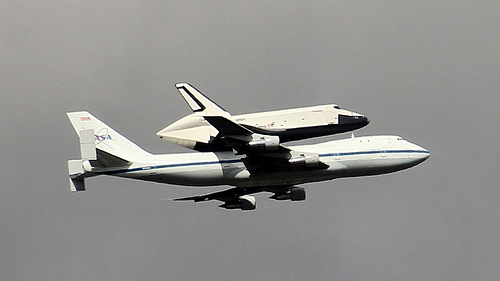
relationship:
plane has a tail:
[66, 110, 431, 209] [66, 110, 153, 164]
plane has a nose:
[66, 110, 431, 209] [404, 141, 431, 170]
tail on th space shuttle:
[174, 81, 232, 118] [156, 81, 369, 151]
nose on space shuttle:
[347, 111, 370, 130] [156, 81, 369, 151]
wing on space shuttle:
[202, 114, 255, 135] [156, 81, 369, 151]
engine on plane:
[284, 151, 320, 169] [66, 110, 431, 209]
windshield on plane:
[395, 137, 405, 141] [66, 110, 431, 209]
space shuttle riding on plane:
[156, 81, 369, 151] [66, 110, 431, 209]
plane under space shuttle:
[66, 110, 431, 209] [156, 81, 369, 151]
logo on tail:
[92, 126, 114, 146] [66, 110, 153, 164]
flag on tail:
[80, 116, 92, 121] [66, 110, 153, 164]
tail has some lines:
[174, 81, 232, 118] [175, 81, 229, 114]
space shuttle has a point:
[156, 81, 369, 151] [155, 123, 178, 143]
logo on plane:
[92, 126, 114, 146] [66, 110, 431, 209]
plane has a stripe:
[66, 110, 431, 209] [94, 149, 430, 176]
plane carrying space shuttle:
[66, 110, 431, 209] [156, 81, 369, 151]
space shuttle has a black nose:
[156, 81, 369, 151] [404, 141, 431, 170]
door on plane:
[380, 144, 389, 156] [66, 110, 431, 209]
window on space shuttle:
[333, 104, 341, 110] [156, 81, 369, 151]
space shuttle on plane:
[156, 81, 369, 151] [66, 110, 431, 209]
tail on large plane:
[66, 110, 153, 164] [66, 110, 431, 209]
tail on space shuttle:
[174, 81, 232, 118] [156, 81, 369, 151]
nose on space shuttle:
[404, 141, 431, 170] [156, 81, 369, 151]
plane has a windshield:
[66, 110, 431, 209] [395, 137, 405, 141]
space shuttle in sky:
[156, 81, 369, 151] [0, 0, 499, 280]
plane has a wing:
[66, 110, 431, 209] [203, 116, 291, 157]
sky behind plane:
[0, 0, 499, 280] [66, 110, 431, 209]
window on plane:
[333, 104, 341, 110] [66, 110, 431, 209]